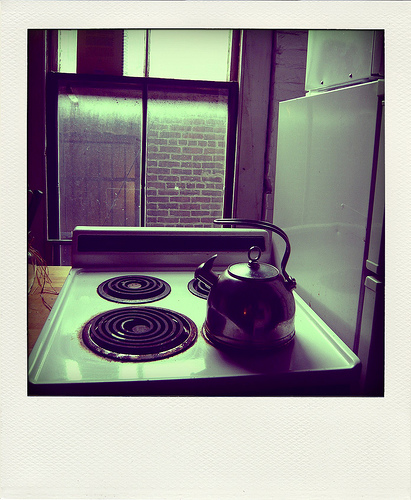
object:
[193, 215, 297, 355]
kettle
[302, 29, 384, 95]
appliance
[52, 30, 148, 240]
window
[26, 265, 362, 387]
stove top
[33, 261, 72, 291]
smoke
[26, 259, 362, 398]
stove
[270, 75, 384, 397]
fridge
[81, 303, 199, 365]
electric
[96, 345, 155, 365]
rust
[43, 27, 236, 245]
building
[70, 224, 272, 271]
counter